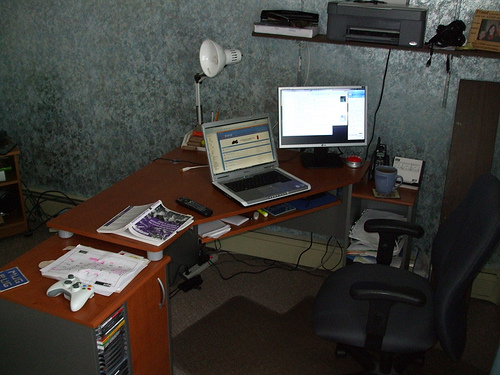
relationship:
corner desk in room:
[51, 122, 425, 262] [0, 0, 500, 374]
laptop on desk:
[201, 112, 318, 214] [139, 164, 228, 223]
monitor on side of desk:
[266, 82, 381, 157] [26, 105, 380, 370]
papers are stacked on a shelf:
[342, 198, 404, 267] [328, 232, 418, 278]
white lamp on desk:
[189, 36, 241, 155] [1, 140, 498, 373]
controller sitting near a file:
[51, 277, 88, 307] [5, 245, 165, 372]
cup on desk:
[370, 165, 401, 198] [8, 140, 302, 372]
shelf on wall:
[245, 0, 490, 66] [247, 5, 484, 149]